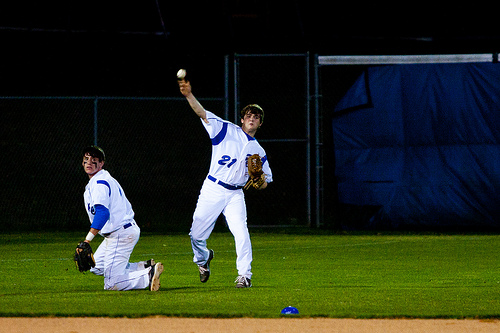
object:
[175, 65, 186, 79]
baseball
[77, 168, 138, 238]
baseball shirt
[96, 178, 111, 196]
blue trim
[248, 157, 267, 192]
catcher mitt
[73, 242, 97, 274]
catcher mitt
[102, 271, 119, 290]
knee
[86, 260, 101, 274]
knee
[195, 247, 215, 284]
foot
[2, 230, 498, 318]
ground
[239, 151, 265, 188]
brown mitt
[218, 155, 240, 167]
numbers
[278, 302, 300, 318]
helmet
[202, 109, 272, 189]
shirt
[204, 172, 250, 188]
belt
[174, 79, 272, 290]
boy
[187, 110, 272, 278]
uniform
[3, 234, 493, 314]
grass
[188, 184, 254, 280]
pants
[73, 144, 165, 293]
boy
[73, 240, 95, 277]
glove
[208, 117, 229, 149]
trim